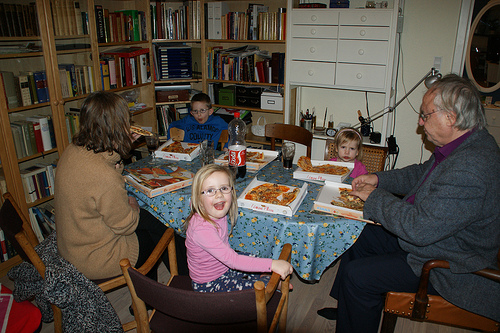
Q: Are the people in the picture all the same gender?
A: No, they are both male and female.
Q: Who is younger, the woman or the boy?
A: The boy is younger than the woman.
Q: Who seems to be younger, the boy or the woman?
A: The boy is younger than the woman.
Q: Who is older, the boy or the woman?
A: The woman is older than the boy.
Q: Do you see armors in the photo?
A: No, there are no armors.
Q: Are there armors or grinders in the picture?
A: No, there are no armors or grinders.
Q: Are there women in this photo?
A: Yes, there is a woman.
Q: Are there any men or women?
A: Yes, there is a woman.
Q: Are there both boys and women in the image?
A: Yes, there are both a woman and a boy.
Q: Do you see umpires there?
A: No, there are no umpires.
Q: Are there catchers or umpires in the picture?
A: No, there are no umpires or catchers.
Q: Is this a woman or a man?
A: This is a woman.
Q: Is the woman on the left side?
A: Yes, the woman is on the left of the image.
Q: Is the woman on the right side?
A: No, the woman is on the left of the image.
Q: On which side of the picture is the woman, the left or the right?
A: The woman is on the left of the image.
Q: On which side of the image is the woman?
A: The woman is on the left of the image.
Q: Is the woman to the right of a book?
A: Yes, the woman is to the right of a book.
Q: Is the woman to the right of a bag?
A: No, the woman is to the right of a book.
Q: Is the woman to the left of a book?
A: No, the woman is to the right of a book.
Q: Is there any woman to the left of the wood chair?
A: Yes, there is a woman to the left of the chair.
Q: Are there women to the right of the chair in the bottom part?
A: No, the woman is to the left of the chair.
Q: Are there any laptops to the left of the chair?
A: No, there is a woman to the left of the chair.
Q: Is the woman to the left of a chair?
A: Yes, the woman is to the left of a chair.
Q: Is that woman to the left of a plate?
A: No, the woman is to the left of a chair.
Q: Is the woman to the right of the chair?
A: No, the woman is to the left of the chair.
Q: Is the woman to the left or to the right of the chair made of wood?
A: The woman is to the left of the chair.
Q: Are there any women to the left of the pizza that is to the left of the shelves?
A: Yes, there is a woman to the left of the pizza.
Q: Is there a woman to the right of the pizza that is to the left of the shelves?
A: No, the woman is to the left of the pizza.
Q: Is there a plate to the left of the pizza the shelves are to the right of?
A: No, there is a woman to the left of the pizza.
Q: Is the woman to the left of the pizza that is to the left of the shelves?
A: Yes, the woman is to the left of the pizza.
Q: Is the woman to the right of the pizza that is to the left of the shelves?
A: No, the woman is to the left of the pizza.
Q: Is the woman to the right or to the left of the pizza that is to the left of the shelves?
A: The woman is to the left of the pizza.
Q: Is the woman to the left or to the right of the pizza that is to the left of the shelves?
A: The woman is to the left of the pizza.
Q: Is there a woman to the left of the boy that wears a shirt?
A: Yes, there is a woman to the left of the boy.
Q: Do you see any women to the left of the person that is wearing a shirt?
A: Yes, there is a woman to the left of the boy.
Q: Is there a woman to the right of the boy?
A: No, the woman is to the left of the boy.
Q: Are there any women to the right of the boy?
A: No, the woman is to the left of the boy.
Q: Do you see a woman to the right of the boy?
A: No, the woman is to the left of the boy.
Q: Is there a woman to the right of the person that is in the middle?
A: No, the woman is to the left of the boy.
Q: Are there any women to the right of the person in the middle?
A: No, the woman is to the left of the boy.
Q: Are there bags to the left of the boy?
A: No, there is a woman to the left of the boy.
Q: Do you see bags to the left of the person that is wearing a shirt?
A: No, there is a woman to the left of the boy.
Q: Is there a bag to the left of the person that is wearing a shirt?
A: No, there is a woman to the left of the boy.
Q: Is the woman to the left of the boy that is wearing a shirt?
A: Yes, the woman is to the left of the boy.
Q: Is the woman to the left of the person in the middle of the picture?
A: Yes, the woman is to the left of the boy.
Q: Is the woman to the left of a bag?
A: No, the woman is to the left of the boy.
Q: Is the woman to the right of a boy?
A: No, the woman is to the left of a boy.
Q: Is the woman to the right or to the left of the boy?
A: The woman is to the left of the boy.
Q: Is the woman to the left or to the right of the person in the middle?
A: The woman is to the left of the boy.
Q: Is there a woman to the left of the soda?
A: Yes, there is a woman to the left of the soda.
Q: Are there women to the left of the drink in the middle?
A: Yes, there is a woman to the left of the soda.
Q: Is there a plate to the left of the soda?
A: No, there is a woman to the left of the soda.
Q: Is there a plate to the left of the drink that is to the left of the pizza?
A: No, there is a woman to the left of the soda.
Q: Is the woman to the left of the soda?
A: Yes, the woman is to the left of the soda.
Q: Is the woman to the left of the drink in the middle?
A: Yes, the woman is to the left of the soda.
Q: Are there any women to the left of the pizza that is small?
A: Yes, there is a woman to the left of the pizza.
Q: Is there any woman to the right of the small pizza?
A: No, the woman is to the left of the pizza.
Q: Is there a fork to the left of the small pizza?
A: No, there is a woman to the left of the pizza.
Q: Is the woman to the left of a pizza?
A: Yes, the woman is to the left of a pizza.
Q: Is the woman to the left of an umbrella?
A: No, the woman is to the left of a pizza.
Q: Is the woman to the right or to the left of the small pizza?
A: The woman is to the left of the pizza.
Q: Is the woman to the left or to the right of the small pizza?
A: The woman is to the left of the pizza.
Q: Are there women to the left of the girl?
A: Yes, there is a woman to the left of the girl.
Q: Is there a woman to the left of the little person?
A: Yes, there is a woman to the left of the girl.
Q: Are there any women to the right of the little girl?
A: No, the woman is to the left of the girl.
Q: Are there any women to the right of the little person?
A: No, the woman is to the left of the girl.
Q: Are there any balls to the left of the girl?
A: No, there is a woman to the left of the girl.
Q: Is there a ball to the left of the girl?
A: No, there is a woman to the left of the girl.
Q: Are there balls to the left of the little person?
A: No, there is a woman to the left of the girl.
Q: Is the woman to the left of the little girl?
A: Yes, the woman is to the left of the girl.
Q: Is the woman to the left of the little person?
A: Yes, the woman is to the left of the girl.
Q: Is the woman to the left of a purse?
A: No, the woman is to the left of the girl.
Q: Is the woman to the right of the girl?
A: No, the woman is to the left of the girl.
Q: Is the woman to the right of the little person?
A: No, the woman is to the left of the girl.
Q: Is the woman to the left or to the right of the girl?
A: The woman is to the left of the girl.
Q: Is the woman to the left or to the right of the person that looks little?
A: The woman is to the left of the girl.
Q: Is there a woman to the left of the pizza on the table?
A: Yes, there is a woman to the left of the pizza.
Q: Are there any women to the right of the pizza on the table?
A: No, the woman is to the left of the pizza.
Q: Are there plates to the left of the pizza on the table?
A: No, there is a woman to the left of the pizza.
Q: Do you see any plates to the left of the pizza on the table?
A: No, there is a woman to the left of the pizza.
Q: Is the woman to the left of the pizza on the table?
A: Yes, the woman is to the left of the pizza.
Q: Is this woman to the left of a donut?
A: No, the woman is to the left of the pizza.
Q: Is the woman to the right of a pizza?
A: No, the woman is to the left of a pizza.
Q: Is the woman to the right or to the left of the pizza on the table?
A: The woman is to the left of the pizza.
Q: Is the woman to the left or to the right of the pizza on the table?
A: The woman is to the left of the pizza.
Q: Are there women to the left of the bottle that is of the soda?
A: Yes, there is a woman to the left of the bottle.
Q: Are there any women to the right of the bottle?
A: No, the woman is to the left of the bottle.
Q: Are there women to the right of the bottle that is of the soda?
A: No, the woman is to the left of the bottle.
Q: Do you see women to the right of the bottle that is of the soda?
A: No, the woman is to the left of the bottle.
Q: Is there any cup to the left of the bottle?
A: No, there is a woman to the left of the bottle.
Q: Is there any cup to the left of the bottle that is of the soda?
A: No, there is a woman to the left of the bottle.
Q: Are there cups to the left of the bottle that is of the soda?
A: No, there is a woman to the left of the bottle.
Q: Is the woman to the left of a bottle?
A: Yes, the woman is to the left of a bottle.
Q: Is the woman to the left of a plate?
A: No, the woman is to the left of a bottle.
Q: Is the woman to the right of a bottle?
A: No, the woman is to the left of a bottle.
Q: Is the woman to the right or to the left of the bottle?
A: The woman is to the left of the bottle.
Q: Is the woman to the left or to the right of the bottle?
A: The woman is to the left of the bottle.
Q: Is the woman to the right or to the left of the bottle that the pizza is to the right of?
A: The woman is to the left of the bottle.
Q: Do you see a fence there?
A: No, there are no fences.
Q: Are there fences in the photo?
A: No, there are no fences.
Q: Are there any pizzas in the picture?
A: Yes, there is a pizza.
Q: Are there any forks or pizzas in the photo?
A: Yes, there is a pizza.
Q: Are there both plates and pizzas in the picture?
A: No, there is a pizza but no plates.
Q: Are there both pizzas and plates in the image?
A: No, there is a pizza but no plates.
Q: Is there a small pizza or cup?
A: Yes, there is a small pizza.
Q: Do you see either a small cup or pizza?
A: Yes, there is a small pizza.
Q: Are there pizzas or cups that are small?
A: Yes, the pizza is small.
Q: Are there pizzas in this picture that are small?
A: Yes, there is a small pizza.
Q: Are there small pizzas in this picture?
A: Yes, there is a small pizza.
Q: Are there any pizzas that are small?
A: Yes, there is a pizza that is small.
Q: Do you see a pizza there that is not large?
A: Yes, there is a small pizza.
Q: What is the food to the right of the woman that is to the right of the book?
A: The food is a pizza.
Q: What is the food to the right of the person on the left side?
A: The food is a pizza.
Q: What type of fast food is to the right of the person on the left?
A: The food is a pizza.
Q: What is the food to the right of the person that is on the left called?
A: The food is a pizza.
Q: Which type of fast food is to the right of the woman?
A: The food is a pizza.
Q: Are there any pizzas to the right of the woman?
A: Yes, there is a pizza to the right of the woman.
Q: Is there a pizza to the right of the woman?
A: Yes, there is a pizza to the right of the woman.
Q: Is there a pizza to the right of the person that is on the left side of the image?
A: Yes, there is a pizza to the right of the woman.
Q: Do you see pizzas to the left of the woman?
A: No, the pizza is to the right of the woman.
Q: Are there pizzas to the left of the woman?
A: No, the pizza is to the right of the woman.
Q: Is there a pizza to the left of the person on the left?
A: No, the pizza is to the right of the woman.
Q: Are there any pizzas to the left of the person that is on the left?
A: No, the pizza is to the right of the woman.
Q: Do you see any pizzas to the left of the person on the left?
A: No, the pizza is to the right of the woman.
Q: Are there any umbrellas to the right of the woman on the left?
A: No, there is a pizza to the right of the woman.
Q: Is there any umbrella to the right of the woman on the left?
A: No, there is a pizza to the right of the woman.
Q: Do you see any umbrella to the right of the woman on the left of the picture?
A: No, there is a pizza to the right of the woman.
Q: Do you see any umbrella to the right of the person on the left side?
A: No, there is a pizza to the right of the woman.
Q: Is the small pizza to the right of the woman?
A: Yes, the pizza is to the right of the woman.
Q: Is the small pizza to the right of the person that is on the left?
A: Yes, the pizza is to the right of the woman.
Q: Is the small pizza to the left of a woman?
A: No, the pizza is to the right of a woman.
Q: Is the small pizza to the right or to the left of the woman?
A: The pizza is to the right of the woman.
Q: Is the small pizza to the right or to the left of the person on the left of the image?
A: The pizza is to the right of the woman.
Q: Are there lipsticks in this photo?
A: No, there are no lipsticks.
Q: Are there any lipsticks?
A: No, there are no lipsticks.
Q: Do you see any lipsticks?
A: No, there are no lipsticks.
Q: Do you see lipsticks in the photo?
A: No, there are no lipsticks.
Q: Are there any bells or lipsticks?
A: No, there are no lipsticks or bells.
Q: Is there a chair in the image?
A: Yes, there is a chair.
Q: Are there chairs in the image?
A: Yes, there is a chair.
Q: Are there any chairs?
A: Yes, there is a chair.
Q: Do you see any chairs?
A: Yes, there is a chair.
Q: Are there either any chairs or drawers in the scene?
A: Yes, there is a chair.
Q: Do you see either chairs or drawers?
A: Yes, there is a chair.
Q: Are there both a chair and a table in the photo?
A: Yes, there are both a chair and a table.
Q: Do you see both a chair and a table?
A: Yes, there are both a chair and a table.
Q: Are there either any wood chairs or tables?
A: Yes, there is a wood chair.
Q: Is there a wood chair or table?
A: Yes, there is a wood chair.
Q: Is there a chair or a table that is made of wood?
A: Yes, the chair is made of wood.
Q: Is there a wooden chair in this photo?
A: Yes, there is a wood chair.